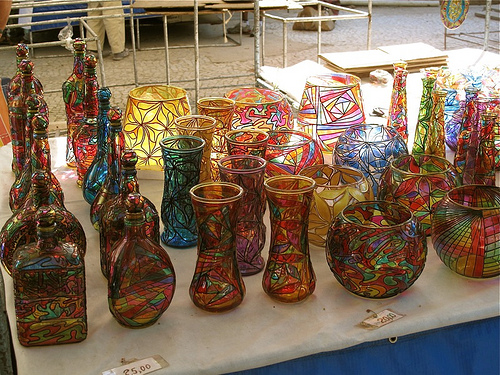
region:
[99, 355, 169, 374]
25 dollar price tag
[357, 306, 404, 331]
20 dollar price tag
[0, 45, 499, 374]
White table with glass vases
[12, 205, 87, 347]
Multi colored glass vase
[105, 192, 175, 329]
Multi colored glass vase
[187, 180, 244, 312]
Multi colored glass vase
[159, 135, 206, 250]
Blue glass vase on table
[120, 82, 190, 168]
Round yellow glass vase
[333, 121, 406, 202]
Round blue glass vase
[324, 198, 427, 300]
Round multi colored glass vase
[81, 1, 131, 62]
Person standing in background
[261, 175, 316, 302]
Multi colored glass vase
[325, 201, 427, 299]
Circular multi colored glass vase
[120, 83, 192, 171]
Yellow circular glass vase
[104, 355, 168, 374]
Price tag for 25 dollars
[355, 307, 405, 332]
Price tag for 20 dollars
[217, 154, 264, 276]
Purple glass vase on table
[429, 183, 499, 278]
Round multi colored glass vase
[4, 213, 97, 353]
glassware on a table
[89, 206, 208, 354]
glassware on a table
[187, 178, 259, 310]
glassware on a table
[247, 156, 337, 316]
glassware on a table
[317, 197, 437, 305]
glassware on a table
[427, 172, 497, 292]
glassware on a table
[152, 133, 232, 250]
glassware on a table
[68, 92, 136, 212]
glassware on a table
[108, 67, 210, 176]
glassware on a table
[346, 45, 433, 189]
glassware on a table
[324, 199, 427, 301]
Multi colored glass vase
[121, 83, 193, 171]
Yellow glass vase on table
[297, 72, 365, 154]
Multi colored glass vase